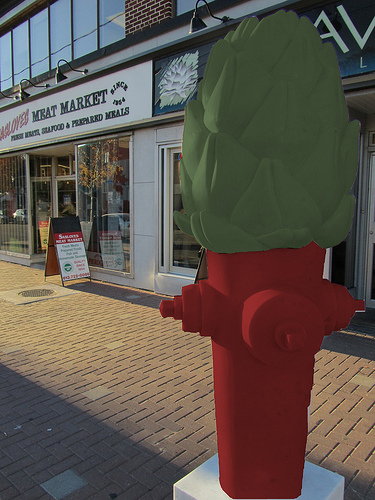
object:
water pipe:
[159, 240, 365, 498]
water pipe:
[159, 0, 365, 499]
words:
[32, 89, 108, 123]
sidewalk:
[0, 259, 375, 499]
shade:
[2, 362, 191, 499]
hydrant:
[159, 6, 365, 500]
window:
[157, 142, 204, 279]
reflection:
[172, 152, 207, 269]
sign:
[44, 215, 92, 287]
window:
[74, 136, 131, 275]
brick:
[124, 0, 177, 38]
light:
[55, 59, 88, 85]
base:
[173, 451, 345, 500]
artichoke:
[173, 9, 360, 253]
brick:
[327, 430, 361, 448]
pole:
[57, 58, 85, 70]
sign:
[0, 60, 154, 152]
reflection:
[77, 135, 131, 273]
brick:
[157, 8, 180, 18]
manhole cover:
[18, 289, 57, 298]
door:
[54, 177, 78, 219]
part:
[122, 289, 143, 303]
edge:
[0, 363, 189, 499]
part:
[66, 280, 173, 309]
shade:
[65, 280, 375, 360]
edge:
[238, 247, 312, 499]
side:
[303, 242, 365, 494]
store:
[0, 120, 151, 291]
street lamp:
[18, 78, 50, 102]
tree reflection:
[174, 10, 361, 253]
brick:
[347, 371, 374, 388]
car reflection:
[86, 215, 126, 273]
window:
[47, 1, 75, 71]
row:
[0, 1, 127, 92]